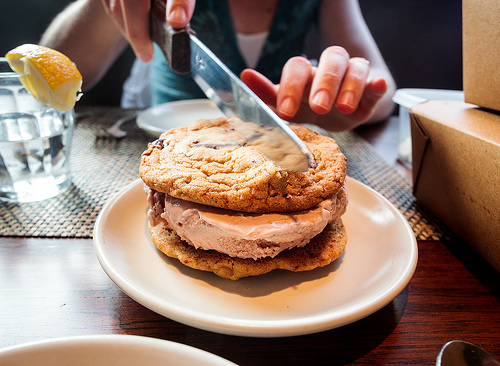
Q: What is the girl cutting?
A: A cookie ice cream sandwich.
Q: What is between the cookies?
A: Ice cream.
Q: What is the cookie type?
A: Chocolate chip.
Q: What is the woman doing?
A: Cutting.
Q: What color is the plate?
A: White.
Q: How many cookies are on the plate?
A: Two.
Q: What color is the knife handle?
A: Black.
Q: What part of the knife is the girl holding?
A: The handle.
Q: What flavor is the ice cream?
A: Chocolate.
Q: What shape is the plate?
A: A circle.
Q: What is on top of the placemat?
A: A glass.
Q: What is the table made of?
A: Wood.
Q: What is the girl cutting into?
A: Cookie sandwich.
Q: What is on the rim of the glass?
A: Lemon wedge.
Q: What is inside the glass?
A: Water.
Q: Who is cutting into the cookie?
A: A girl.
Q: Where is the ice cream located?
A: Between the cookies.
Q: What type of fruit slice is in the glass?
A: An orange slice.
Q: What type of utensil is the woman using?
A: A knife.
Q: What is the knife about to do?
A: Cut into the ice cream sandwich.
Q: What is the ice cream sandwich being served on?
A: A plate.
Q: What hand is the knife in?
A: The right one.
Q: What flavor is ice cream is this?
A: Chocolate.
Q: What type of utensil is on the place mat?
A: A fork.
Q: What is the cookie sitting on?
A: Plate.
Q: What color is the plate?
A: White.